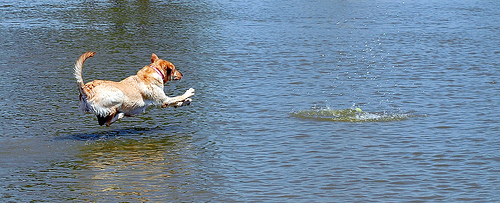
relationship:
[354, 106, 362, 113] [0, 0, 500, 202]
ball in water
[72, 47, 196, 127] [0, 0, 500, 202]
dog jumping into water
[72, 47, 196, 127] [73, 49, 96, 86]
dog has tail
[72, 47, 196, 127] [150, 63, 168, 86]
dog wearing collar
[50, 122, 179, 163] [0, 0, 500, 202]
reflection of dog in water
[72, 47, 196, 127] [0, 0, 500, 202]
dog jumped into water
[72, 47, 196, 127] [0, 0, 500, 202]
dog jumping over water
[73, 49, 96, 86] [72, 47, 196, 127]
tail curled toward dog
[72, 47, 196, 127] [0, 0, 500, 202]
dog close to water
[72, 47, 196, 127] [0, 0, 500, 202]
dog surrounded by water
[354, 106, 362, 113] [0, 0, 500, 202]
ball splashing in water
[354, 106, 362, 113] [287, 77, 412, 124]
ball made splash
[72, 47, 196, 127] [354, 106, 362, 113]
dog chasing ball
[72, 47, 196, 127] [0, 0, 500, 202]
dog jumping in water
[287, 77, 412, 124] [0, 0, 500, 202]
splash in water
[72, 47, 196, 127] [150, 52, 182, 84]
dog has head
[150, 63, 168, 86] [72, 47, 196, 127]
collar on dog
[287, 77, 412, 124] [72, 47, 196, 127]
splash in front of dog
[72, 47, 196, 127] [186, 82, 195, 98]
dog has paw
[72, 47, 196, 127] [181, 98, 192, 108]
dog has paw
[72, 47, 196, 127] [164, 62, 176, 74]
dog has ear